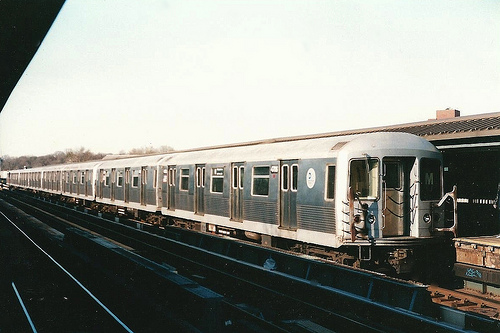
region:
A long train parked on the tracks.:
[8, 126, 483, 256]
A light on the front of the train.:
[416, 205, 436, 227]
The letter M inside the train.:
[420, 165, 442, 194]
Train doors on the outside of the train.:
[276, 155, 303, 237]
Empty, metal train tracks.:
[5, 182, 235, 332]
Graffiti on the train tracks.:
[459, 260, 489, 287]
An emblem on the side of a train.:
[301, 162, 322, 197]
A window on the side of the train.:
[175, 163, 195, 196]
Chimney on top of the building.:
[428, 99, 468, 126]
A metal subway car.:
[163, 143, 461, 258]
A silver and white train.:
[6, 129, 458, 281]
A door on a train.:
[195, 163, 205, 216]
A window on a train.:
[256, 165, 268, 195]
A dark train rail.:
[1, 210, 132, 332]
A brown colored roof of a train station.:
[128, 113, 499, 140]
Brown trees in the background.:
[1, 143, 173, 168]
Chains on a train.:
[383, 178, 415, 218]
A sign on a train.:
[306, 165, 317, 189]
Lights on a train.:
[423, 211, 440, 223]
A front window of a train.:
[350, 158, 377, 198]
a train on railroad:
[4, 132, 474, 317]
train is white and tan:
[1, 122, 468, 276]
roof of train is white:
[10, 121, 437, 163]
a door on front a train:
[375, 152, 422, 244]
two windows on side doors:
[341, 149, 446, 247]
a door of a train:
[270, 155, 306, 232]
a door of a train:
[221, 156, 245, 227]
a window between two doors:
[225, 156, 310, 236]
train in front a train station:
[351, 101, 498, 278]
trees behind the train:
[1, 142, 186, 182]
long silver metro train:
[15, 151, 425, 242]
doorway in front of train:
[389, 151, 403, 243]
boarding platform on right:
[454, 211, 491, 249]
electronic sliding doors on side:
[280, 159, 305, 232]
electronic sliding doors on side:
[222, 160, 244, 225]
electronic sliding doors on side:
[189, 157, 209, 229]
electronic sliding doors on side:
[168, 162, 178, 213]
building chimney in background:
[436, 107, 466, 124]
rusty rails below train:
[403, 273, 496, 331]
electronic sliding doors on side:
[112, 165, 137, 198]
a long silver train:
[3, 155, 462, 266]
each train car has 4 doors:
[158, 144, 385, 251]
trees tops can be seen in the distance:
[8, 140, 170, 169]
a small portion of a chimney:
[429, 100, 467, 124]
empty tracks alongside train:
[1, 185, 221, 330]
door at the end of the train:
[369, 145, 426, 246]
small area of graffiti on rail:
[460, 263, 492, 286]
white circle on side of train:
[298, 160, 325, 200]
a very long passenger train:
[3, 131, 445, 269]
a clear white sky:
[26, 5, 498, 140]